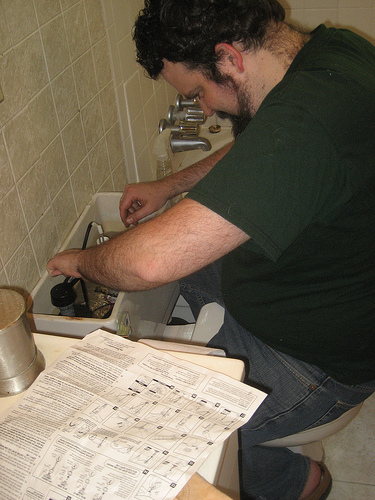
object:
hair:
[129, 0, 286, 87]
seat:
[238, 336, 375, 429]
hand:
[45, 250, 87, 283]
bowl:
[24, 190, 181, 339]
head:
[130, 0, 268, 125]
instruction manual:
[3, 330, 266, 498]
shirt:
[184, 21, 375, 386]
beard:
[211, 88, 253, 140]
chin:
[232, 113, 254, 132]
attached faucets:
[159, 92, 212, 154]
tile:
[322, 392, 373, 482]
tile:
[329, 481, 374, 498]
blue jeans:
[179, 254, 368, 496]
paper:
[2, 328, 267, 494]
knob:
[49, 284, 77, 306]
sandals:
[307, 460, 333, 498]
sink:
[30, 330, 75, 368]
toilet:
[21, 188, 363, 466]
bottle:
[156, 141, 174, 180]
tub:
[183, 123, 232, 180]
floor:
[313, 409, 375, 500]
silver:
[159, 103, 201, 145]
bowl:
[0, 286, 41, 393]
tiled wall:
[1, 1, 182, 300]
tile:
[15, 160, 52, 234]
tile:
[60, 108, 88, 176]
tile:
[61, 1, 92, 66]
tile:
[90, 33, 113, 92]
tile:
[104, 116, 125, 172]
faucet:
[167, 135, 211, 152]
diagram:
[1, 328, 269, 498]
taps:
[159, 118, 177, 136]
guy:
[45, 0, 375, 500]